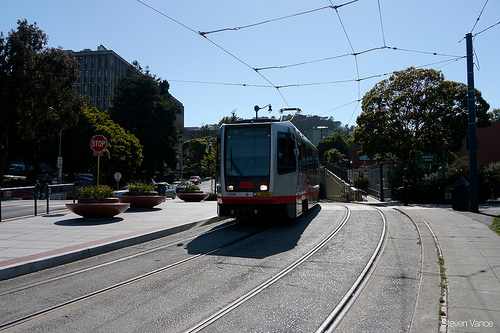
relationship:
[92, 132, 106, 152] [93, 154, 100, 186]
sign on pole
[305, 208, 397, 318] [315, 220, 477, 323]
tracks built into road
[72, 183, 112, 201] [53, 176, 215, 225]
plant on side street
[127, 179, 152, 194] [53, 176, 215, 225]
plant on side street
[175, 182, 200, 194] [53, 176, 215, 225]
plant on side street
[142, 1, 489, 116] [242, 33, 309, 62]
powerlines are in net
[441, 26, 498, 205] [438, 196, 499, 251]
pole on street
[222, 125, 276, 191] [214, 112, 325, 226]
windshield on muni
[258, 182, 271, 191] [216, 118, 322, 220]
head light on car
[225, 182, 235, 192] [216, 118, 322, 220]
head light on car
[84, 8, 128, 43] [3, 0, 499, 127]
clouds are in sky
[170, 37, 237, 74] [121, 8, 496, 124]
clouds are in sky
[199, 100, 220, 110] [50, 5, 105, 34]
clouds are in sky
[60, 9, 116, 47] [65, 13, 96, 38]
clouds are in sky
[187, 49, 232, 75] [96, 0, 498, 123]
clouds are in blue sky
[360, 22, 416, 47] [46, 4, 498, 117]
clouds are in sky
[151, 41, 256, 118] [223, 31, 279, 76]
clouds are in sky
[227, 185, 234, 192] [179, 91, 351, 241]
head light on train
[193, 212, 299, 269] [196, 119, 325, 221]
shadow on train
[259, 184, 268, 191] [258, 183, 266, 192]
head light on train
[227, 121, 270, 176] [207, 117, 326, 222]
front window on train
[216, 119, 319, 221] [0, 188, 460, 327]
car in track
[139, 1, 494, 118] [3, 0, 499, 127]
wire in sky